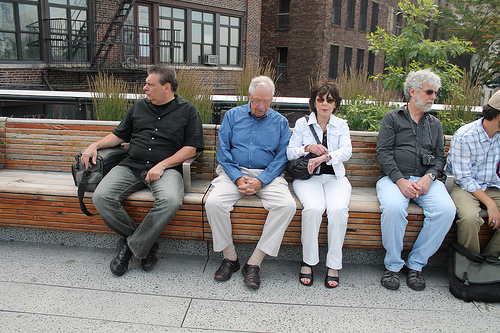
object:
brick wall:
[95, 1, 123, 69]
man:
[204, 75, 297, 289]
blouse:
[286, 111, 354, 179]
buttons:
[157, 117, 161, 120]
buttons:
[155, 128, 159, 131]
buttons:
[148, 148, 152, 151]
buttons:
[147, 161, 150, 164]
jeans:
[375, 176, 457, 274]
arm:
[91, 102, 134, 150]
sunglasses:
[316, 97, 336, 104]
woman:
[285, 82, 353, 289]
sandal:
[299, 259, 314, 286]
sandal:
[324, 267, 340, 289]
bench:
[0, 116, 500, 256]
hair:
[402, 68, 441, 103]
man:
[376, 67, 457, 291]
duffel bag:
[71, 143, 131, 217]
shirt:
[110, 94, 205, 178]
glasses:
[419, 87, 440, 96]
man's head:
[403, 70, 441, 113]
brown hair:
[309, 80, 342, 114]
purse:
[285, 115, 322, 180]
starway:
[27, 0, 182, 73]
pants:
[205, 164, 297, 258]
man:
[79, 62, 205, 278]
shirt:
[216, 100, 292, 189]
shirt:
[444, 116, 500, 193]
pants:
[292, 174, 353, 271]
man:
[444, 89, 500, 276]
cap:
[487, 88, 500, 110]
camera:
[421, 154, 436, 166]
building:
[0, 0, 263, 125]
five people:
[81, 62, 500, 304]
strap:
[404, 106, 435, 156]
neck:
[404, 97, 426, 124]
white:
[285, 112, 353, 270]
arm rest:
[181, 151, 203, 193]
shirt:
[375, 104, 447, 183]